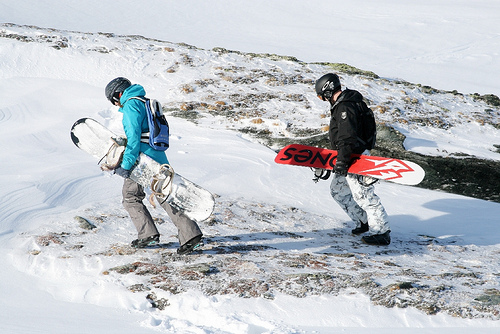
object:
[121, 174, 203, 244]
man`s pant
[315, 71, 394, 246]
man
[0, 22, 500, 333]
snow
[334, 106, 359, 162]
arm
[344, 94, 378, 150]
backpack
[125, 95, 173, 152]
backpack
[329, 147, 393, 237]
pants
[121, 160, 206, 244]
pants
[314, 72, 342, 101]
helmet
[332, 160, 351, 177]
hand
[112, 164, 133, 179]
hand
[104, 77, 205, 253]
man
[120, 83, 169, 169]
jacket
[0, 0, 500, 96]
clouds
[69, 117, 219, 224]
snowboard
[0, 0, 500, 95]
sky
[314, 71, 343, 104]
head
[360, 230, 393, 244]
foot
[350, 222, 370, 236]
foot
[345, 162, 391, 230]
leg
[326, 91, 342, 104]
neck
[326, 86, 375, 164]
coat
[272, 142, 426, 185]
snowboard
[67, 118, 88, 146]
part